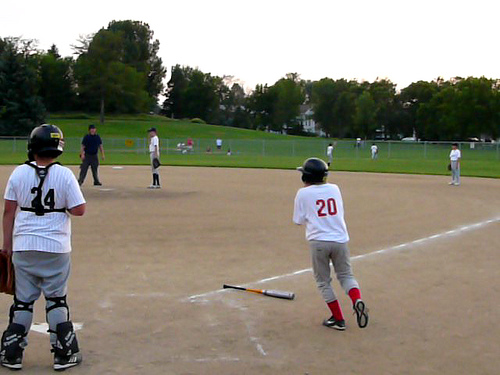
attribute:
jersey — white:
[271, 189, 402, 300]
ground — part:
[89, 210, 290, 359]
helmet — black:
[26, 122, 65, 158]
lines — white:
[87, 215, 491, 372]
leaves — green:
[1, 19, 499, 147]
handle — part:
[214, 278, 254, 303]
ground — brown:
[0, 165, 500, 373]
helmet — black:
[298, 156, 325, 178]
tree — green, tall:
[60, 26, 168, 123]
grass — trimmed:
[0, 98, 498, 175]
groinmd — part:
[101, 286, 278, 373]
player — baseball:
[281, 150, 402, 348]